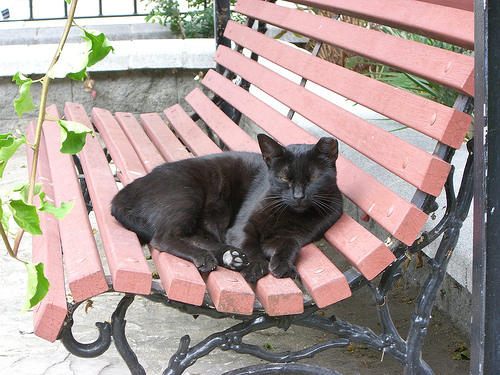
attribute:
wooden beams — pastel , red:
[33, 7, 470, 312]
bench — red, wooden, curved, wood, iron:
[24, 1, 496, 373]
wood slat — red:
[38, 103, 109, 303]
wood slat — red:
[59, 100, 151, 305]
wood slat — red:
[220, 21, 469, 156]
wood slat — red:
[233, 0, 473, 92]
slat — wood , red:
[20, 120, 64, 345]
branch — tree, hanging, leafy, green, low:
[0, 0, 114, 310]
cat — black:
[104, 133, 346, 280]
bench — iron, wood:
[71, 55, 461, 355]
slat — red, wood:
[41, 93, 151, 302]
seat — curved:
[91, 39, 450, 316]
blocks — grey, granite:
[3, 45, 198, 114]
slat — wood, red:
[65, 100, 174, 289]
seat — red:
[30, 30, 490, 343]